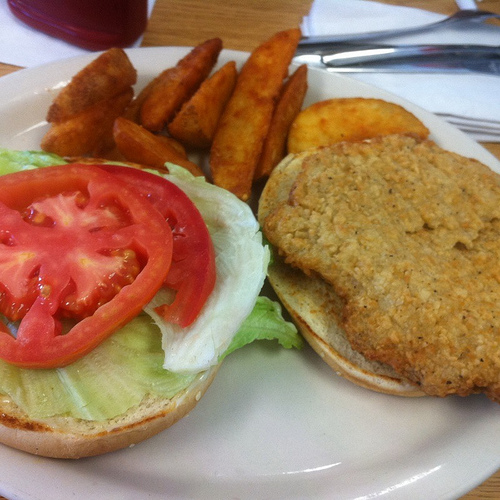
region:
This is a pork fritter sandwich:
[268, 132, 484, 404]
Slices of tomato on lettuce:
[8, 247, 198, 338]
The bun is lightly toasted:
[43, 403, 218, 442]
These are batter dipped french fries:
[107, 66, 276, 177]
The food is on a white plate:
[244, 421, 418, 461]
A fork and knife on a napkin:
[325, 12, 492, 81]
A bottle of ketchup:
[16, 0, 167, 60]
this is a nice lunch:
[144, 217, 468, 332]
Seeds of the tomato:
[87, 263, 139, 308]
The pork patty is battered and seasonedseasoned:
[422, 342, 463, 389]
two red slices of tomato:
[2, 157, 217, 376]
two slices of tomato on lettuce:
[3, 160, 220, 372]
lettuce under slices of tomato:
[3, 152, 217, 377]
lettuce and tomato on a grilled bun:
[1, 150, 271, 460]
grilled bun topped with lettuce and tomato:
[3, 147, 272, 465]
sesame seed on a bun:
[191, 388, 204, 403]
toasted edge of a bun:
[1, 410, 173, 445]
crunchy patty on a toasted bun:
[260, 137, 498, 398]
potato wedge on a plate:
[290, 98, 432, 143]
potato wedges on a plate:
[40, 25, 434, 200]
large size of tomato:
[0, 166, 173, 368]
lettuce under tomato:
[3, 151, 301, 419]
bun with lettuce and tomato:
[1, 151, 262, 458]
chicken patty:
[269, 135, 496, 398]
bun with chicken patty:
[256, 151, 496, 403]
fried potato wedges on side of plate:
[42, 29, 429, 194]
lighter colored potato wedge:
[288, 97, 430, 146]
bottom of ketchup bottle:
[7, 1, 150, 46]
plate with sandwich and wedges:
[0, 44, 499, 497]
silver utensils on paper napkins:
[294, 6, 497, 67]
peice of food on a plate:
[0, 141, 184, 386]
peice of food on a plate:
[42, 39, 149, 131]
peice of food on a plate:
[42, 86, 142, 158]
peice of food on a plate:
[110, 111, 205, 191]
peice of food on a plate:
[123, 31, 230, 133]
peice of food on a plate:
[164, 53, 247, 150]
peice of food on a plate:
[198, 16, 305, 216]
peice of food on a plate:
[248, 62, 315, 189]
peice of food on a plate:
[270, 84, 439, 166]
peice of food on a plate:
[257, 117, 499, 390]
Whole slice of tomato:
[1, 175, 165, 362]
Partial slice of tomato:
[168, 163, 218, 315]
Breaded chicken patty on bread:
[289, 151, 499, 378]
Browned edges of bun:
[0, 411, 49, 436]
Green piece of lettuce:
[246, 297, 296, 350]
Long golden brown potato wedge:
[227, 28, 268, 189]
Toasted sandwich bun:
[295, 290, 341, 365]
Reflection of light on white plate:
[283, 463, 340, 475]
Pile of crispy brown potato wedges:
[51, 52, 136, 157]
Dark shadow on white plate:
[453, 397, 488, 413]